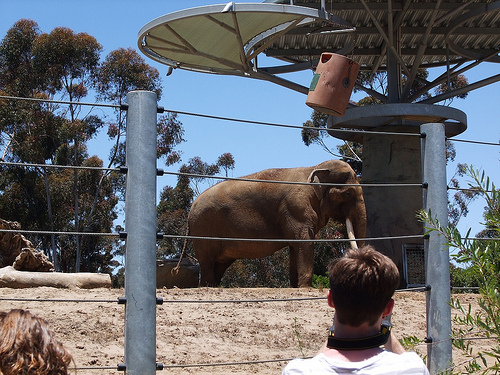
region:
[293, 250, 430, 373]
person holding an electronic recording device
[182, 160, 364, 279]
brownish grey elephant standing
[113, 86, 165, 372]
metallic pole holding wires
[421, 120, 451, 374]
metallic pole holding wires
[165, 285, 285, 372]
ground made of tan dirt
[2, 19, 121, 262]
tall trees with leaves seen in background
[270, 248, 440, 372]
person wearing white t-shirt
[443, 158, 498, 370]
green vegetation near fence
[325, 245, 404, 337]
person with dark short hair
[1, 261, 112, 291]
tree trunk laying on the ground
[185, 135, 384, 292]
elephant in the zoo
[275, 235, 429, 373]
man looking at the elephant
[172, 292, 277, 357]
dirt ground of an elephant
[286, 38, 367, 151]
feeding station for an elephant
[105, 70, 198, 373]
steel pole of a fence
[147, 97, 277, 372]
wire fence at a zoo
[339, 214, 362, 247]
tusk of an elephant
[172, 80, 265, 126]
blue sky in the distance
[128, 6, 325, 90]
shaded roof for an elephant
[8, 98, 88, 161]
green leaves on a tree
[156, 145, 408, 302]
elephant standing on the dirt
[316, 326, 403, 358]
strap around the neck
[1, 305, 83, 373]
back of someone's head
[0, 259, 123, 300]
log laying on the dirt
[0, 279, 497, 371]
dirt on the ground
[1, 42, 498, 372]
elephant in an enclosure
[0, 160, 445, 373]
people looking at the elephant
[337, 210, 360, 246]
long white tusk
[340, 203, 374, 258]
tusk on the side of the trunk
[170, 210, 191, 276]
tail is hanging down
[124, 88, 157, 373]
round metal fence pole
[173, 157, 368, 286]
large mature brown-gray elephant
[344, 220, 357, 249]
ivory elephant tusk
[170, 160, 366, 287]
dusty elephant after dust bath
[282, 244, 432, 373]
young man watching elephant through fence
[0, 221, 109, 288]
deat tree parts in elephant compound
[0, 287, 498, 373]
dirt ground in elephant compound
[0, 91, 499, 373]
metal post and wire barrier fence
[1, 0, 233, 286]
tall trees in wild animal park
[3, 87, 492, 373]
two persons watching elephant from behind fence